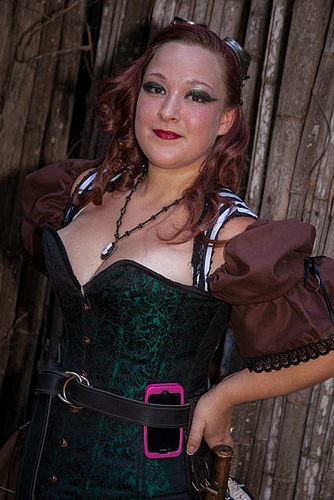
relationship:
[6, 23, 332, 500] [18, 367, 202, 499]
woman wearing a belt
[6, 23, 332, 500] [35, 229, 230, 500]
woman wearing a corset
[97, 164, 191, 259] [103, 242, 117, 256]
necklace with a figure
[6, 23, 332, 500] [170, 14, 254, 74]
woman has goggles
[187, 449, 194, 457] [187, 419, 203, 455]
nail on thumb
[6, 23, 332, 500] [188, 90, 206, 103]
woman has eye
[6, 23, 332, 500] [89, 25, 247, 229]
woman has hair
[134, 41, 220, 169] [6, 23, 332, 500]
face of woman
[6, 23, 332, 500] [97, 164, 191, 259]
woman wearing a necklace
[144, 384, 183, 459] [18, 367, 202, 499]
cell phone on belt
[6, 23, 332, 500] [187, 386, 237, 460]
woman has a hand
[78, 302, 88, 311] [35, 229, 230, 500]
button on corset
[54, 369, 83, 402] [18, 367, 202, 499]
ring on belt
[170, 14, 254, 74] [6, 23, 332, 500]
goggles on top of woman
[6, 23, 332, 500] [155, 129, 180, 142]
woman has lipstick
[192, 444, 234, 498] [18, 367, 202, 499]
sword on belt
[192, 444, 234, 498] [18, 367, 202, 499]
sword hanging from belt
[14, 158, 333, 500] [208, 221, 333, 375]
dress has sleeve